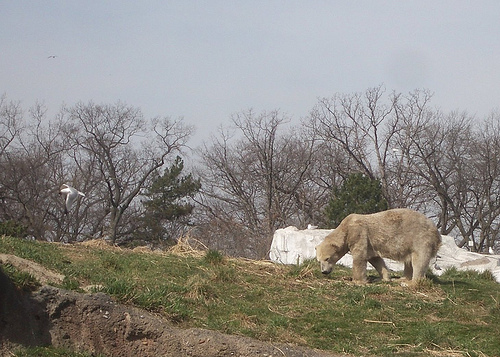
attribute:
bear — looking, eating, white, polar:
[330, 207, 452, 282]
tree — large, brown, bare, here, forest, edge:
[125, 138, 149, 243]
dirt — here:
[118, 327, 143, 339]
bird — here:
[58, 185, 86, 206]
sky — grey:
[127, 4, 250, 57]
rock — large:
[3, 278, 97, 340]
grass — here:
[107, 265, 232, 292]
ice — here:
[277, 245, 301, 258]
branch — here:
[3, 151, 103, 202]